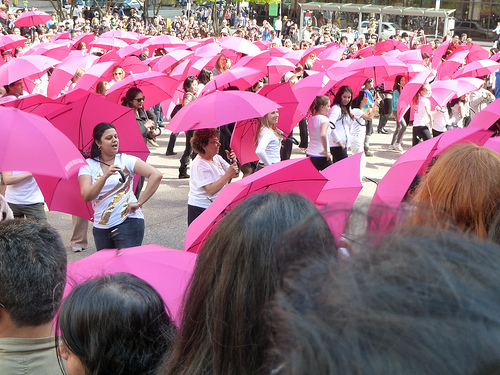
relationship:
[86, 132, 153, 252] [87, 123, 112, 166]
woman has hair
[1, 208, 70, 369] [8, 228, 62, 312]
man has hair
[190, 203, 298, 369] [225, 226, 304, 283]
person has head